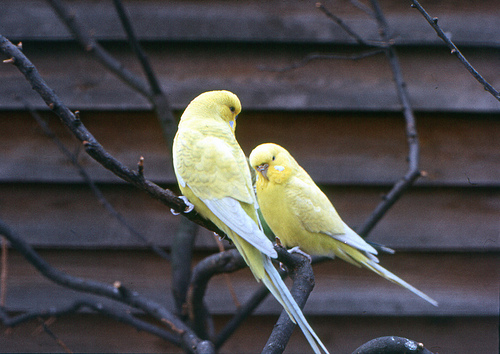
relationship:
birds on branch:
[166, 87, 442, 330] [1, 4, 457, 337]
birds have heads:
[166, 87, 442, 330] [177, 78, 297, 185]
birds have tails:
[166, 87, 442, 330] [221, 224, 464, 351]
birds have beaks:
[166, 87, 442, 330] [235, 112, 277, 179]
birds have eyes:
[166, 87, 442, 330] [228, 102, 279, 161]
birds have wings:
[166, 87, 442, 330] [192, 159, 373, 252]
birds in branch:
[166, 87, 442, 330] [1, 4, 457, 337]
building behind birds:
[1, 1, 499, 353] [166, 87, 442, 330]